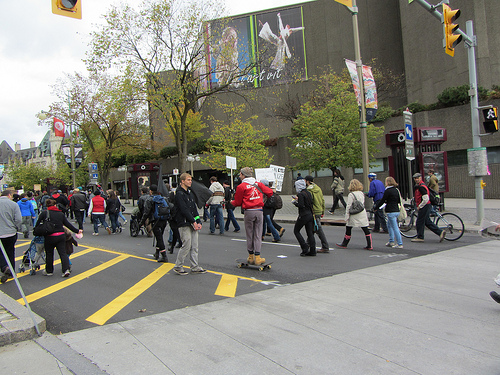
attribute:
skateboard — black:
[237, 255, 276, 278]